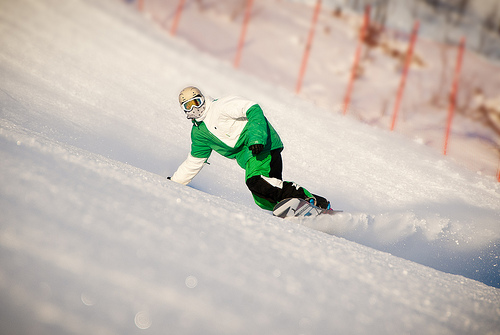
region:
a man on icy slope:
[164, 86, 347, 222]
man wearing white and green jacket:
[171, 94, 286, 186]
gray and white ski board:
[272, 194, 347, 230]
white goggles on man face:
[181, 94, 205, 112]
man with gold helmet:
[177, 84, 203, 104]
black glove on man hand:
[246, 141, 276, 163]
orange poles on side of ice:
[132, 0, 498, 182]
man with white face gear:
[184, 98, 209, 123]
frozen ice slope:
[0, 0, 498, 333]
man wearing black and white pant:
[245, 147, 330, 222]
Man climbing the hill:
[140, 80, 357, 250]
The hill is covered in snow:
[22, 97, 152, 264]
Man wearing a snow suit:
[180, 92, 309, 194]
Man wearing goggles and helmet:
[173, 85, 209, 118]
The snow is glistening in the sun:
[124, 175, 236, 301]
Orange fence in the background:
[234, 27, 474, 152]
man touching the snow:
[140, 138, 203, 225]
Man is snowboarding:
[146, 29, 349, 222]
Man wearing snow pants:
[232, 165, 375, 217]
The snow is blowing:
[313, 172, 495, 269]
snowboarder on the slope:
[133, 70, 360, 242]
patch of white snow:
[160, 285, 201, 314]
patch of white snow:
[327, 288, 353, 314]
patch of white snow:
[366, 217, 398, 239]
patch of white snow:
[101, 155, 133, 182]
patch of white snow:
[226, 243, 264, 278]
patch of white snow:
[43, 155, 62, 178]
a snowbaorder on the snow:
[121, 55, 493, 303]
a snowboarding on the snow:
[136, 45, 343, 301]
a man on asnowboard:
[67, 57, 482, 309]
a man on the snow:
[114, 58, 375, 324]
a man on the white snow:
[85, 4, 328, 334]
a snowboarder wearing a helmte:
[122, 65, 413, 290]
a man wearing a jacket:
[143, 36, 298, 217]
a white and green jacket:
[189, 107, 302, 201]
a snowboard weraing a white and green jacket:
[155, 39, 347, 285]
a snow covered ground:
[57, 87, 290, 333]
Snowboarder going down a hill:
[168, 84, 331, 226]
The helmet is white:
[175, 87, 207, 119]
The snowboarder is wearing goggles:
[178, 89, 210, 119]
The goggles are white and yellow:
[176, 96, 208, 113]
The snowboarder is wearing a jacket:
[167, 87, 293, 184]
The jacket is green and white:
[168, 94, 283, 176]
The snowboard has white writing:
[275, 195, 346, 230]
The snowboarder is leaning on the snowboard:
[171, 85, 340, 226]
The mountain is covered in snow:
[3, 3, 490, 333]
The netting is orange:
[158, 2, 495, 162]